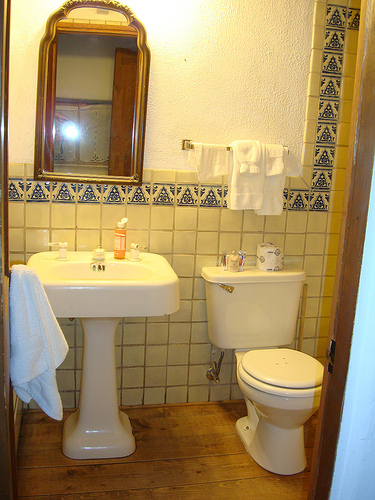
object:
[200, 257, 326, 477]
toilet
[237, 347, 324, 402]
lid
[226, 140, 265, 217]
towel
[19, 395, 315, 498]
floor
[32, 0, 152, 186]
mirror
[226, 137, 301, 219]
towels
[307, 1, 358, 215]
tiles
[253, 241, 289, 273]
toilet paper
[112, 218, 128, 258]
bottle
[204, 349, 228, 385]
hookup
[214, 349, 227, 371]
intake hose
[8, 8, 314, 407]
wall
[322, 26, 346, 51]
triangles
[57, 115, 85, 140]
reflection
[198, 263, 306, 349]
tank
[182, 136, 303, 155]
rack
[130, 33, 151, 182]
trim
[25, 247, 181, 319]
sink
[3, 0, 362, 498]
bathroom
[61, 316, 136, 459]
pedestal